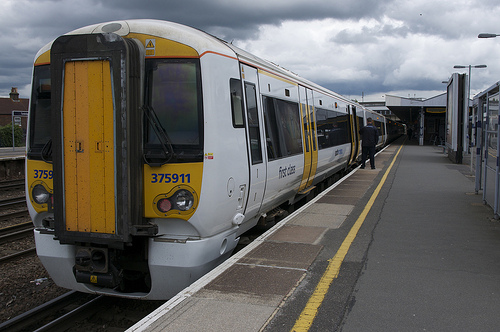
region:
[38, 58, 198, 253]
front of yellow train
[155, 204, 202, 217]
head lamp on train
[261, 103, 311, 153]
dark windows on train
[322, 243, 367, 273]
yellow line on platform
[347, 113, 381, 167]
person standing by train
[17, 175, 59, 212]
right head light of a train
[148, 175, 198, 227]
left head light of a train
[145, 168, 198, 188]
Number 375911 on front of train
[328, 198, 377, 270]
Yellow safety line painted on pavement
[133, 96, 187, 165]
windshield wiper on train window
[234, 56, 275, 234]
Door on the side of a train compartment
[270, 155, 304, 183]
First class written on side of train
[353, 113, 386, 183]
Man standing on train platform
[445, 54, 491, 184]
Street lights at train station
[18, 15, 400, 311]
A yellow and white train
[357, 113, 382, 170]
A person standing near the train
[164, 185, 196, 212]
The left headlight of the train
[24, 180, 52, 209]
The right headlight of the train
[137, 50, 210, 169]
A window on the train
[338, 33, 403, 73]
Part of the cloudy sky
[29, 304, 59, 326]
Part of the train tracks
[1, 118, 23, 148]
A green tree in distance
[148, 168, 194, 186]
Numbers on the train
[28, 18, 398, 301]
train parked at station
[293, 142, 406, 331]
line marks where passengers should stand while waiting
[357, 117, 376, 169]
conductor stands next to the train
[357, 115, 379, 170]
man stands between train and yellow stripe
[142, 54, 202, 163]
window is on the train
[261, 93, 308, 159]
window looks out from the train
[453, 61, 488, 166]
streetlight is turned off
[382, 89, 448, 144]
structure allows passengers to remain out of the sun and rain while waiting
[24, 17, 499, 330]
train station is rather empty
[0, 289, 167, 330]
train tracks under train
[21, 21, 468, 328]
train on track next to platform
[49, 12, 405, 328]
white train on track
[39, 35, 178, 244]
yellow door on train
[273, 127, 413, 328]
yellow line on platform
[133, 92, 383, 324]
white line on platform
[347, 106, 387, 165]
man standing next to train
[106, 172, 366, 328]
multicolored patched on platform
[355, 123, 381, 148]
person wearing dark top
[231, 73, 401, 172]
multiple windows on side of train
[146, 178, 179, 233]
red lights on train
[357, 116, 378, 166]
a man standing next to the train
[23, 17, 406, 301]
white and yellow train at the station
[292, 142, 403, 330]
the yellow line painted on the station floor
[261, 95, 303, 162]
rectangular window on the train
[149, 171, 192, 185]
the number 375911 on the train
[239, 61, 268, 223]
the white door on the train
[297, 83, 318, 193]
yellow double doors on the train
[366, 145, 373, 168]
the man's right leg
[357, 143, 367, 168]
the man's left leg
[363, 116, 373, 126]
the man's head